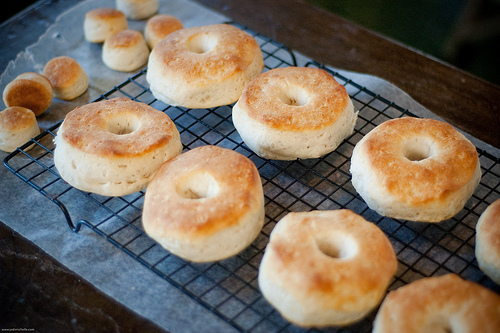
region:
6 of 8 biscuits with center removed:
[368, 117, 462, 211]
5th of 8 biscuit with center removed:
[251, 195, 372, 299]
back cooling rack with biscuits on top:
[179, 280, 216, 312]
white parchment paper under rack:
[109, 291, 149, 306]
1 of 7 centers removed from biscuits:
[6, 111, 43, 137]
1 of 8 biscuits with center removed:
[47, 133, 143, 188]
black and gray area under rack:
[20, 274, 60, 317]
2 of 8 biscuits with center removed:
[163, 40, 223, 93]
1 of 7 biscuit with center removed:
[393, 295, 495, 328]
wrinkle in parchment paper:
[32, 218, 72, 271]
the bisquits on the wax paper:
[1, 1, 56, 153]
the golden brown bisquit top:
[106, 27, 132, 47]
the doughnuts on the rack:
[54, 75, 499, 330]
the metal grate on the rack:
[270, 165, 333, 202]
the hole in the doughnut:
[400, 133, 435, 172]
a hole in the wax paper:
[53, 32, 70, 44]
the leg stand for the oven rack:
[56, 201, 91, 238]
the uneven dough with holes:
[78, 153, 145, 193]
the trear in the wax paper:
[26, 14, 67, 51]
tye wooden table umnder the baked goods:
[297, 0, 492, 48]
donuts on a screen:
[20, 14, 479, 319]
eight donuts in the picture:
[84, 41, 495, 318]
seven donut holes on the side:
[15, 5, 170, 140]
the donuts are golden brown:
[114, 68, 434, 261]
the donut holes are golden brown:
[2, 56, 92, 155]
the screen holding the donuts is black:
[8, 159, 233, 314]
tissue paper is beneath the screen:
[18, 150, 259, 321]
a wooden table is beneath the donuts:
[27, 47, 490, 296]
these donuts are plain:
[13, 15, 420, 330]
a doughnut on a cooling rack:
[259, 205, 400, 330]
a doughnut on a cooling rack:
[346, 114, 486, 228]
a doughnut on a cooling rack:
[229, 64, 359, 164]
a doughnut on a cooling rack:
[143, 142, 264, 265]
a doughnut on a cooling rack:
[51, 96, 179, 194]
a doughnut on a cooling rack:
[139, 23, 264, 110]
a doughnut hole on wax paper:
[0, 105, 43, 150]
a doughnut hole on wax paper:
[3, 73, 52, 118]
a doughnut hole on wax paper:
[36, 52, 89, 99]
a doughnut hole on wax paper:
[99, 26, 150, 73]